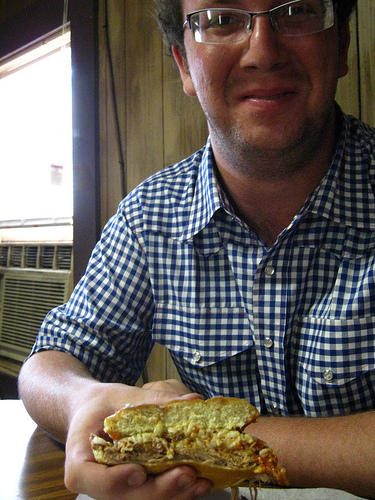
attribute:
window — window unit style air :
[1, 23, 75, 244]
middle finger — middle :
[118, 461, 199, 499]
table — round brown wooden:
[0, 397, 24, 498]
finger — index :
[46, 449, 154, 495]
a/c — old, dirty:
[0, 225, 84, 389]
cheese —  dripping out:
[228, 454, 289, 498]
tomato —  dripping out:
[253, 437, 286, 486]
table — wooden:
[4, 397, 252, 498]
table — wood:
[0, 402, 240, 497]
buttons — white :
[238, 248, 291, 392]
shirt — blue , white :
[111, 174, 353, 344]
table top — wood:
[0, 393, 371, 498]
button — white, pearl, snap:
[260, 334, 273, 349]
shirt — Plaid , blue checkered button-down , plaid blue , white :
[42, 120, 373, 421]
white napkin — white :
[218, 487, 368, 499]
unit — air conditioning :
[0, 240, 74, 363]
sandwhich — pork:
[66, 394, 296, 495]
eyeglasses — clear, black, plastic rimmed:
[179, 0, 348, 46]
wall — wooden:
[72, 1, 373, 388]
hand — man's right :
[63, 385, 231, 496]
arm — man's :
[268, 415, 360, 482]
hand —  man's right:
[90, 393, 291, 493]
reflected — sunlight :
[0, 402, 44, 498]